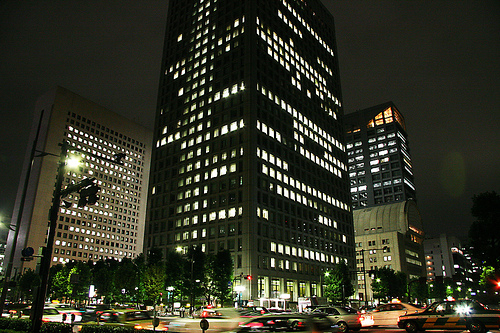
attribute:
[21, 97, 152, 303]
building — tall, rectangular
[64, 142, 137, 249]
windows — rows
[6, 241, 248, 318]
trees — green